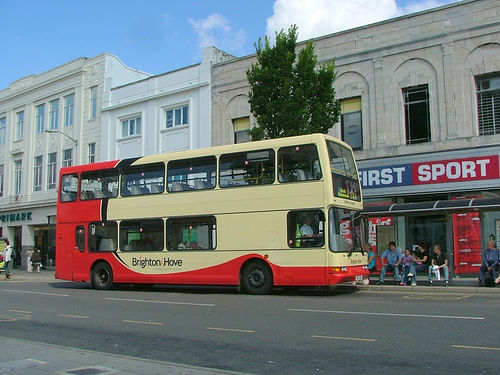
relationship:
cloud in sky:
[188, 12, 249, 62] [2, 1, 462, 90]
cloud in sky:
[262, 0, 402, 46] [2, 1, 462, 90]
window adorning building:
[180, 104, 188, 125] [98, 42, 237, 252]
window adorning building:
[173, 108, 181, 124] [98, 42, 237, 252]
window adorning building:
[164, 109, 174, 129] [98, 42, 237, 252]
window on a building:
[135, 115, 139, 134] [100, 47, 240, 162]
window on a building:
[129, 118, 133, 135] [101, 43, 241, 171]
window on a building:
[122, 118, 129, 136] [100, 47, 240, 162]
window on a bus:
[166, 214, 218, 250] [50, 140, 370, 291]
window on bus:
[61, 171, 80, 202] [50, 140, 370, 291]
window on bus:
[79, 169, 117, 200] [50, 140, 370, 291]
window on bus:
[120, 160, 164, 195] [50, 140, 370, 291]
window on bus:
[168, 155, 215, 192] [50, 140, 370, 291]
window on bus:
[218, 146, 276, 186] [50, 140, 370, 291]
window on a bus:
[86, 220, 124, 252] [50, 140, 370, 291]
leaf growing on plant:
[264, 89, 294, 109] [250, 31, 335, 126]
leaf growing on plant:
[273, 77, 313, 107] [245, 34, 335, 134]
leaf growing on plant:
[273, 77, 280, 82] [250, 25, 335, 134]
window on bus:
[284, 207, 323, 247] [50, 140, 370, 291]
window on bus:
[86, 220, 117, 250] [50, 140, 370, 291]